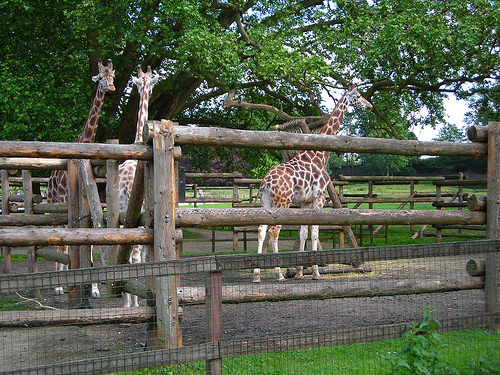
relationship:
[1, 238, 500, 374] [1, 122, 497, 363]
net below fence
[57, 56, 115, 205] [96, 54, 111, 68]
giraffe has antlers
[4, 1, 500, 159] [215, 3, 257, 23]
tree has branch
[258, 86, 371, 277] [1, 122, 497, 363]
giraffe at zoo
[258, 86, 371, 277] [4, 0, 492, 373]
giraffe at zoo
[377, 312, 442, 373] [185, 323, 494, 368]
bush on lawn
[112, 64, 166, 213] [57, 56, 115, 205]
giraffe next to giraffe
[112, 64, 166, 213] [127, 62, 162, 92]
giraffe has head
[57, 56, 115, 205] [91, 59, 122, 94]
giraffe has head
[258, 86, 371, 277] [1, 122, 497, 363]
giraffe behind fence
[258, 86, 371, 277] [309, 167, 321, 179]
giraffe has spot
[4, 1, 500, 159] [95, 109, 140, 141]
tree has trunk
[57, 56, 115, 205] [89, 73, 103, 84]
giraffe has ear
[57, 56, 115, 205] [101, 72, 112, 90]
giraffe has face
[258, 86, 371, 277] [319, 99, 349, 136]
giraffe has neck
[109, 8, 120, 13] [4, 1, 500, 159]
leaf on tree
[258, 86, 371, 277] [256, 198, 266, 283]
giraffe has leg